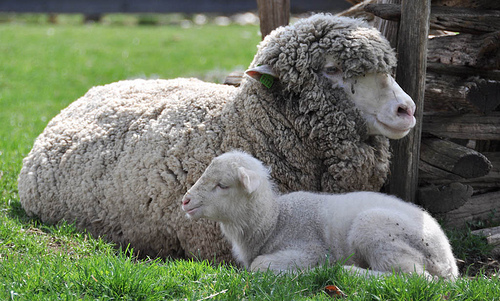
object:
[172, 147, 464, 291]
baby lamb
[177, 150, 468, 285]
lamb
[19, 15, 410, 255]
sheep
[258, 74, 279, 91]
tag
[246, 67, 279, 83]
ear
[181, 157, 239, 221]
face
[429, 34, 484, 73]
wood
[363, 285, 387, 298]
grass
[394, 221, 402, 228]
spot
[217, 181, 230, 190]
eye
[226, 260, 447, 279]
down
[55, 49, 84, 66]
patch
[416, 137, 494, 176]
pile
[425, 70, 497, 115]
logs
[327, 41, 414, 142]
face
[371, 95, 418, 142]
muzzle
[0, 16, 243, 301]
field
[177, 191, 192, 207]
nose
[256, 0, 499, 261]
structure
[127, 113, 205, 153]
wool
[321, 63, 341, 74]
eye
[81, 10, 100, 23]
cow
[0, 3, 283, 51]
distance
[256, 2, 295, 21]
fence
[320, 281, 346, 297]
leaf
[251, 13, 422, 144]
head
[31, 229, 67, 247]
dirt